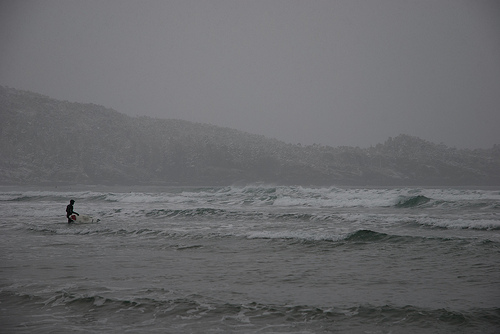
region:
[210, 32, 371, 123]
the sky during the dusk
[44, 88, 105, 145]
the mountains in the distance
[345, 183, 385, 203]
a bunch of forming waves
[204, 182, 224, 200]
the foam of some waves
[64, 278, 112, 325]
waves hitting the shore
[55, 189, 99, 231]
a person wading in the water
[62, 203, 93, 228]
a small white surfboard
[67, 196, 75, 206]
the head of a person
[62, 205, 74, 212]
the torso of a person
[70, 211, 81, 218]
the arm of a person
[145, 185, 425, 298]
lots of waves in the water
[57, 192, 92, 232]
a person with the surfboard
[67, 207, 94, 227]
a person holding white color surfboard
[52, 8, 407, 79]
sky with clouds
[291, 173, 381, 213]
water foam in the sea water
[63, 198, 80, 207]
head of the person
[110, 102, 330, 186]
mountain with trees and plants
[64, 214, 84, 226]
person holding surfboard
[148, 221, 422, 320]
blue color sea water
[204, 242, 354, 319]
small waves in the water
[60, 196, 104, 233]
a man standing in the ocean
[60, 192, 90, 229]
a surfer standing in the ocean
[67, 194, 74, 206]
the head of a man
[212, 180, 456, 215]
waves cresting in the ocean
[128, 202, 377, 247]
waves cresting in the ocean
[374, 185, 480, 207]
waves cresting in the ocean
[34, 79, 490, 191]
a foggy hill on the coast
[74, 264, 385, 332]
grey water in the ocean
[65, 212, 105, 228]
a surfboard in the ocean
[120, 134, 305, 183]
trees growing by the ocean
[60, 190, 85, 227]
the man in the water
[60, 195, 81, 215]
the silhouette of the surfer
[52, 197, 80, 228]
the surfer walking in the water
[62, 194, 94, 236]
the board in the surfers hand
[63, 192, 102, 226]
the surfer holding his surfboard out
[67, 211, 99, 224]
the white surfboard in the mans hand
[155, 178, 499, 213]
the waves in the water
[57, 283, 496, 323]
the tide coming into shore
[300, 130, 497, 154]
the trees on the hilltop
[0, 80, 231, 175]
the hill by the ocean water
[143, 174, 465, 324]
The ocean water is very choppy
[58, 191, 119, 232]
A person getting in the water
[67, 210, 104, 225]
The surfboard is in the man's hands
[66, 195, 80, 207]
The head of the man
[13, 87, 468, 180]
The mountains are very large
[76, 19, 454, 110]
The sky is very smoky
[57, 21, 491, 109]
The sky is the color grey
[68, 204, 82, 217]
The arm of the man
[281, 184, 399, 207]
The water is the color white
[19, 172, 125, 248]
The man is getting ready to surf